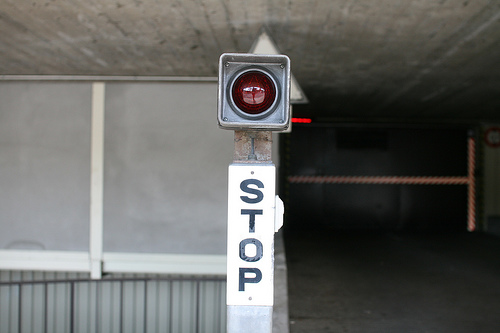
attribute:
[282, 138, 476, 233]
rod — twisted steel, t-shaped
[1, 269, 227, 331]
railing — thin, metal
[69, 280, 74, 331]
spoke — metal, thin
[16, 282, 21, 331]
spoke — metal, thin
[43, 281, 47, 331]
spoke — metal, thin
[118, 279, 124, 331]
spoke — metal, thin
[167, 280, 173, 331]
spoke — metal, thin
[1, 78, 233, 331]
wall — gray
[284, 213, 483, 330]
flooring — dark, concrete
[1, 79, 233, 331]
area — white, paneled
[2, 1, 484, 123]
ceiling — concrete, gray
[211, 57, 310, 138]
light — red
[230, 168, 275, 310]
sign — white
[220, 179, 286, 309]
writing — black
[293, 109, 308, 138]
illumination — red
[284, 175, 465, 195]
line — orange, striped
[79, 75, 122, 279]
line — white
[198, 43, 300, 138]
light — round, red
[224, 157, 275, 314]
sign — white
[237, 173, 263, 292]
letters — black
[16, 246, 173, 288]
frame — white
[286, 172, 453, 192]
pole — horizontal, striped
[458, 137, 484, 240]
pole — striped, verticle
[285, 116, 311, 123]
light — bright, red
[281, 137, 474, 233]
pole barrier — metal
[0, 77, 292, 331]
wall — white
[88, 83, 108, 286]
stripe — vertical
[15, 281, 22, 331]
fence post — small, iron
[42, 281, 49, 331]
fence post — small, iron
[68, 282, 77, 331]
fence post — small, iron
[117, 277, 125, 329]
fence post — small, iron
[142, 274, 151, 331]
fence post — small, iron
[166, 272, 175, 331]
fence post — small, iron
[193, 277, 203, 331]
fence post — small, iron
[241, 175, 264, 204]
letter — black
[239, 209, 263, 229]
letter — black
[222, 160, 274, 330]
post — white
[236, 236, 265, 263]
letter — black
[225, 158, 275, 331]
sign — white, black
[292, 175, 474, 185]
bar — red, white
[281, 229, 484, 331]
road — concrete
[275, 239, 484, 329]
road — concrete, gray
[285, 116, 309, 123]
neon light — red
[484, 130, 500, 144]
sign — red, white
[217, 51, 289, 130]
light — red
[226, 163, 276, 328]
stop sign — vertical, white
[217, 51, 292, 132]
traffic light — camera-like